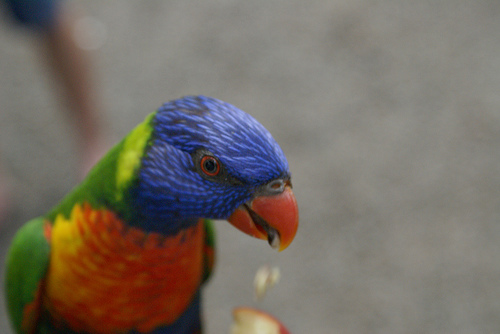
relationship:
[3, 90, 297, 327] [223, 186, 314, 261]
bird has beak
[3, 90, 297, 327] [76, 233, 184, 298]
bird has breast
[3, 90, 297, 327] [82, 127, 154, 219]
bird has neck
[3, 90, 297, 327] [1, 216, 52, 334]
bird has green wing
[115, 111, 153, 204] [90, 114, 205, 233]
strip on neck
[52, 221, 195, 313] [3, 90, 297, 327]
feathers on bird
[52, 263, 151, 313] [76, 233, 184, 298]
feathers on breast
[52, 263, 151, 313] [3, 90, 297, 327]
feathers on bird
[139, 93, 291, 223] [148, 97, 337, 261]
feathers on head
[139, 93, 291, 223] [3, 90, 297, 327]
feathers on bird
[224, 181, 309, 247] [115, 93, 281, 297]
beak of bird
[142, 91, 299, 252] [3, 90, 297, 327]
head of bird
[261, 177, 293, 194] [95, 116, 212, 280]
nostril of bird